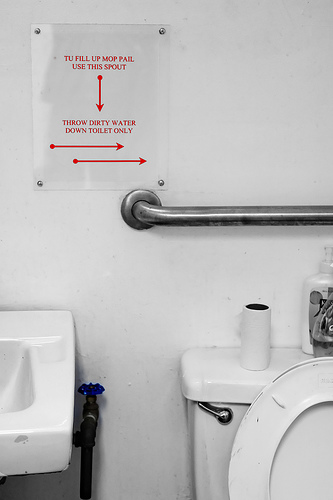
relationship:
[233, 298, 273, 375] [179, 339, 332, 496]
roll on toilet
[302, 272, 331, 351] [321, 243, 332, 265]
bottle has pump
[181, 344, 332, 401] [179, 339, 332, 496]
lid on toilet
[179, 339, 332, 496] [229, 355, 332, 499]
toilet has seat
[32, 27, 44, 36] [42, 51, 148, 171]
bolt holding instructions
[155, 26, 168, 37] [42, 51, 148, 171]
bolt holding instructions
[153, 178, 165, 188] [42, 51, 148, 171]
bolt holding instructions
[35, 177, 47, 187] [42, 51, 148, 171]
bolt holding instructions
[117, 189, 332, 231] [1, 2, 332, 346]
bar on wall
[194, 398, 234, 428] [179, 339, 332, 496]
flusher on toilet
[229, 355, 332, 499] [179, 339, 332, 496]
seat on toilet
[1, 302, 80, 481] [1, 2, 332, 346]
sink on wall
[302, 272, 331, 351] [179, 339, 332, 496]
bottle on toilet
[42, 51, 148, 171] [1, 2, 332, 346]
instructions are on wall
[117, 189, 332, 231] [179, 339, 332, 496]
bar above toilet